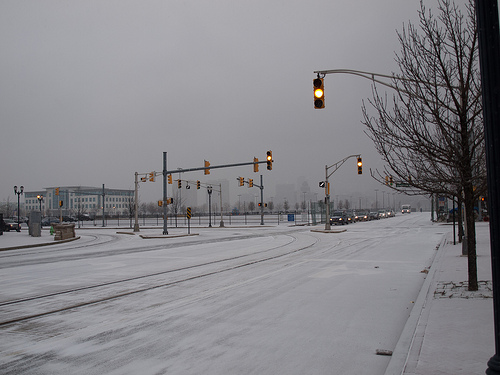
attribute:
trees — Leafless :
[370, 7, 497, 289]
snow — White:
[214, 247, 361, 340]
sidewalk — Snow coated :
[383, 222, 499, 374]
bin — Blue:
[286, 209, 295, 222]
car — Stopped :
[307, 190, 377, 241]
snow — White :
[433, 300, 484, 372]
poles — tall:
[8, 181, 71, 231]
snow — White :
[296, 276, 408, 336]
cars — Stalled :
[346, 184, 483, 231]